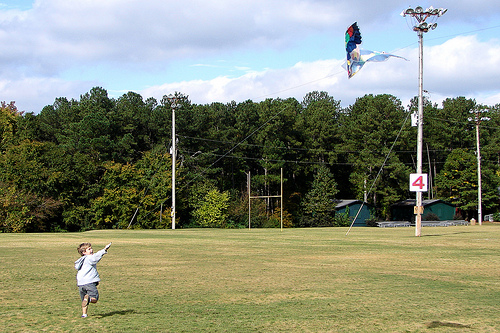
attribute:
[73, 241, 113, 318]
boy — small, young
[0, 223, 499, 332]
field — brown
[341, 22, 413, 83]
kite — flying, colorful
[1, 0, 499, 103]
sky — clear, blue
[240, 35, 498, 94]
clouds — white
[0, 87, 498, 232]
trees — green, tall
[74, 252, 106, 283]
hoodie — gray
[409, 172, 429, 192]
sign — white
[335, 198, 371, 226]
building — green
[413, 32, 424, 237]
post — standing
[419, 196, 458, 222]
house — green